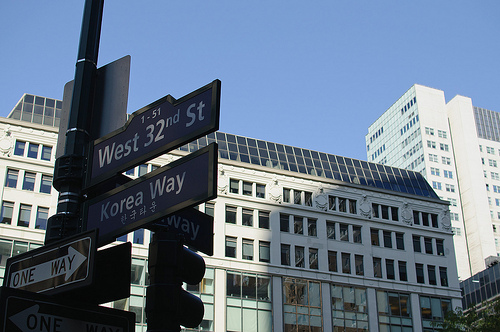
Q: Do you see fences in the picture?
A: No, there are no fences.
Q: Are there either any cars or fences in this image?
A: No, there are no fences or cars.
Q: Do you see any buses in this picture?
A: No, there are no buses.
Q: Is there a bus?
A: No, there are no buses.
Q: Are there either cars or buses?
A: No, there are no buses or cars.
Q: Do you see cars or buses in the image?
A: No, there are no buses or cars.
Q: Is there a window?
A: Yes, there is a window.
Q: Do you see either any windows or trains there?
A: Yes, there is a window.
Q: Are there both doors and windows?
A: No, there is a window but no doors.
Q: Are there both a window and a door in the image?
A: No, there is a window but no doors.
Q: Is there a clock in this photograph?
A: No, there are no clocks.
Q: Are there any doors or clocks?
A: No, there are no clocks or doors.